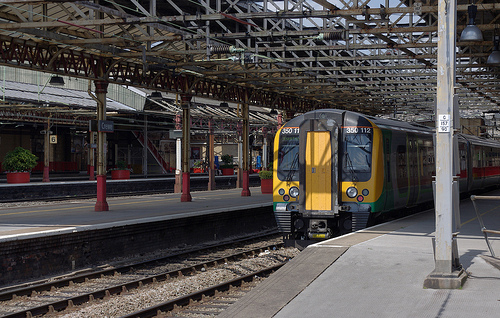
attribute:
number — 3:
[345, 126, 351, 135]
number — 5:
[285, 125, 290, 135]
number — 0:
[289, 127, 295, 135]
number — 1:
[292, 126, 299, 136]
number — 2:
[365, 126, 372, 134]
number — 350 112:
[345, 124, 374, 136]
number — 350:
[344, 124, 360, 134]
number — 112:
[359, 126, 373, 134]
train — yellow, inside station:
[268, 102, 499, 244]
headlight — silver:
[345, 184, 359, 198]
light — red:
[354, 194, 366, 203]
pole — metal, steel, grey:
[429, 0, 466, 274]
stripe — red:
[278, 122, 377, 132]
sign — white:
[46, 134, 59, 146]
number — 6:
[49, 135, 57, 142]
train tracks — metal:
[3, 229, 301, 318]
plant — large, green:
[257, 166, 279, 195]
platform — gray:
[0, 178, 280, 276]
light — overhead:
[48, 72, 69, 89]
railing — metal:
[467, 189, 499, 265]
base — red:
[90, 172, 111, 215]